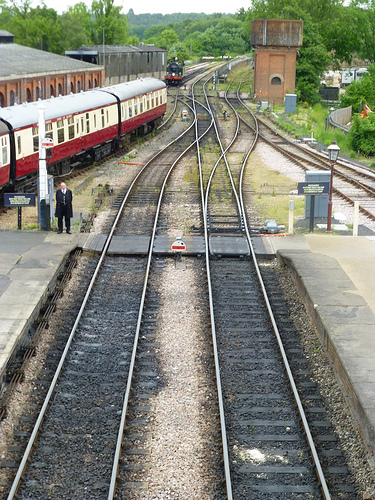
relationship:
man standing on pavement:
[55, 181, 73, 234] [6, 204, 80, 329]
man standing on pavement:
[55, 181, 73, 234] [0, 226, 77, 366]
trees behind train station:
[7, 1, 374, 101] [3, 15, 178, 145]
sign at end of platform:
[294, 180, 331, 198] [287, 233, 374, 498]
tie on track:
[219, 327, 275, 332] [183, 44, 354, 498]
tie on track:
[219, 309, 266, 315] [183, 44, 354, 498]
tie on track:
[218, 299, 258, 306] [183, 44, 354, 498]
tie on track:
[219, 317, 265, 323] [183, 44, 354, 498]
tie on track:
[218, 287, 256, 295] [183, 44, 354, 498]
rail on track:
[0, 53, 375, 500] [183, 44, 354, 498]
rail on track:
[260, 285, 283, 353] [183, 44, 354, 498]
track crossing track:
[190, 54, 320, 494] [10, 50, 210, 498]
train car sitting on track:
[161, 41, 186, 92] [10, 50, 210, 498]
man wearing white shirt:
[55, 181, 73, 234] [60, 188, 65, 194]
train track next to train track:
[76, 198, 133, 483] [190, 200, 309, 477]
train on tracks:
[0, 77, 166, 210] [12, 55, 372, 499]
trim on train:
[11, 155, 55, 171] [0, 73, 185, 201]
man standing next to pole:
[45, 188, 94, 233] [28, 101, 64, 229]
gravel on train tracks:
[0, 65, 369, 498] [0, 56, 373, 498]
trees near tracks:
[7, 1, 374, 101] [12, 55, 372, 499]